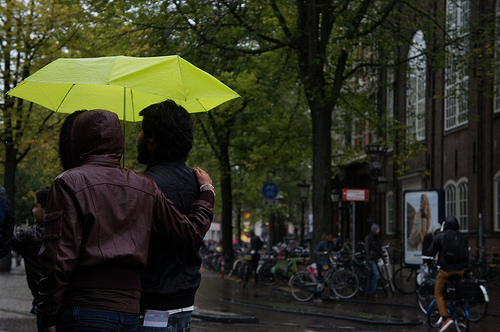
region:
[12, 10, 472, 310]
A rainy day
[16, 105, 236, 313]
Two people walking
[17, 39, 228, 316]
The people are under an umbrella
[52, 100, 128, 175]
This person is wearing a hood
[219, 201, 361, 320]
Many bicycles on the street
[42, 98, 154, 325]
This person has their arms around the man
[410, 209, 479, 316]
This person is on a bike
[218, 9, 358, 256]
Tall trees with green leaves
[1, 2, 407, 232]
tall trees over street and buildings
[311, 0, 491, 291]
dark building with white-paned windows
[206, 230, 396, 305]
bicycles parked in row by curb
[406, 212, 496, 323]
rider in dark jacket on bicycle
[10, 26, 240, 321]
two people under yellow umbrella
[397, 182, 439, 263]
sign featuring a woman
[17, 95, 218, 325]
arm over the shoulder of another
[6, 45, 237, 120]
bent rib on umbrella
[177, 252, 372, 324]
dark and wet road by bicycles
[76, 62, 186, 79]
A yellow umbrella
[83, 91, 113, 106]
The inside surface of the umbrella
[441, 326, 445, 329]
Cyclist's foot on the ground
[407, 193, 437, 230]
An advertisement board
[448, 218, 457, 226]
Head covered with a black hood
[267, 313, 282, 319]
Wet road surface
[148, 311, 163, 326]
A brochure in the back pocket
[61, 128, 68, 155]
Fur on the hood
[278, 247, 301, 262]
Bicycles parked on the street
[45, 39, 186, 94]
Person holding yellow umbrella.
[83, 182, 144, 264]
Person wearing brown coat.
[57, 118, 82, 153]
Black fur on hood.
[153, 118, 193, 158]
Person has short hair.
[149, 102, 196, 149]
Person has black hair.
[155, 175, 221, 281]
Person wearing black coat.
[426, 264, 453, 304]
Person wearing brown pants.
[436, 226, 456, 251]
Person wearing black coat.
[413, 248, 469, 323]
Person riding bike on street.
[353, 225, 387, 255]
Person wearing dark coat.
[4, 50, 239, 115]
man holding yellow umbrella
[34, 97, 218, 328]
peson in leather jacket with arm around man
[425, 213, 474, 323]
person in tan pants sitting on bike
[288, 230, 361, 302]
person caring bike onto sidewalk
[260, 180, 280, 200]
blue and white round sign over bikes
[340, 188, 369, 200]
red and white rectangle sign over bikes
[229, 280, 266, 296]
wet street by bikes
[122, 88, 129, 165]
metal rod on yellow umbrella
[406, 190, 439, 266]
picture of woman modeling by bikes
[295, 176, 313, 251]
black street light pole around bikes